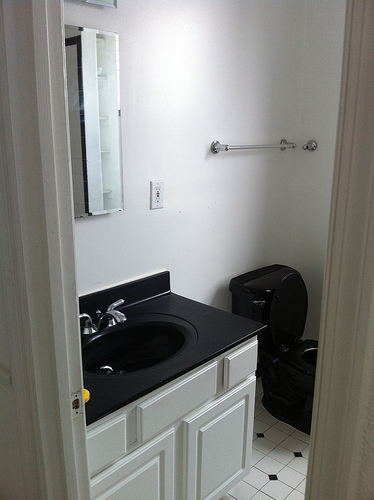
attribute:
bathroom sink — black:
[83, 318, 188, 377]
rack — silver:
[212, 136, 295, 156]